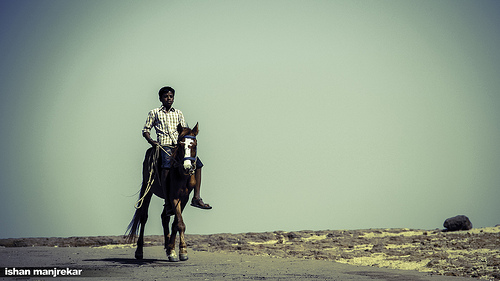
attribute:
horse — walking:
[98, 115, 219, 218]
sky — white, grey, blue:
[327, 53, 431, 130]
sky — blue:
[7, 4, 492, 176]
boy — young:
[142, 86, 212, 209]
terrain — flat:
[0, 227, 500, 278]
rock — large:
[439, 212, 473, 231]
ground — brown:
[9, 217, 494, 277]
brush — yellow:
[97, 220, 493, 280]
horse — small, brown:
[124, 121, 204, 265]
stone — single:
[441, 212, 473, 233]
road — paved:
[2, 244, 457, 279]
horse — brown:
[118, 118, 223, 268]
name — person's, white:
[3, 266, 85, 278]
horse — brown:
[149, 129, 256, 230]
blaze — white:
[183, 136, 194, 175]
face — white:
[173, 124, 200, 182]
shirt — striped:
[143, 106, 189, 146]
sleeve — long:
[143, 107, 158, 133]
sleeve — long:
[176, 111, 186, 128]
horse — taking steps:
[135, 122, 198, 262]